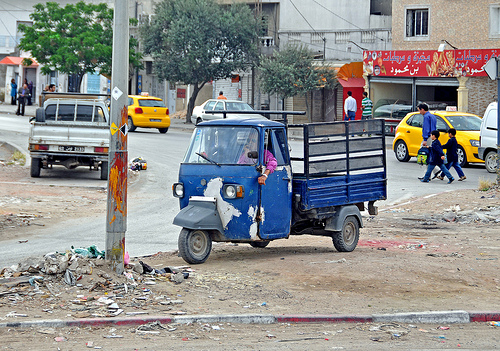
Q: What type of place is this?
A: It is a street.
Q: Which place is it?
A: It is a street.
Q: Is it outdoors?
A: Yes, it is outdoors.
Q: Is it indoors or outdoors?
A: It is outdoors.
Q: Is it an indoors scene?
A: No, it is outdoors.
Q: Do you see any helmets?
A: No, there are no helmets.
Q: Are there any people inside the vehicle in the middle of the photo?
A: Yes, there is a person inside the vehicle.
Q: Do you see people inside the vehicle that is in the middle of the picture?
A: Yes, there is a person inside the vehicle.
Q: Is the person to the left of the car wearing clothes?
A: Yes, the person is wearing clothes.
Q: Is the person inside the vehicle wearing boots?
A: No, the person is wearing clothes.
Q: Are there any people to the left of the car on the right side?
A: Yes, there is a person to the left of the car.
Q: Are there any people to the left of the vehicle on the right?
A: Yes, there is a person to the left of the car.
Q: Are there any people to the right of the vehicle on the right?
A: No, the person is to the left of the car.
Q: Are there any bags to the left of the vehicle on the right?
A: No, there is a person to the left of the car.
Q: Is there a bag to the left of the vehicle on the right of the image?
A: No, there is a person to the left of the car.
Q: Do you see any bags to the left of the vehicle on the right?
A: No, there is a person to the left of the car.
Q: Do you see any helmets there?
A: No, there are no helmets.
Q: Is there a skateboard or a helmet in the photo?
A: No, there are no helmets or skateboards.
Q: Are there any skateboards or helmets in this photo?
A: No, there are no helmets or skateboards.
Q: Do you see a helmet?
A: No, there are no helmets.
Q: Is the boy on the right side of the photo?
A: Yes, the boy is on the right of the image.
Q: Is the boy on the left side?
A: No, the boy is on the right of the image.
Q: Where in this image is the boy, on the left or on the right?
A: The boy is on the right of the image.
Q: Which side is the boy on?
A: The boy is on the right of the image.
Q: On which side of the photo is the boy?
A: The boy is on the right of the image.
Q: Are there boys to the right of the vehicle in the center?
A: Yes, there is a boy to the right of the vehicle.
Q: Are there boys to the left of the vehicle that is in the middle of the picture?
A: No, the boy is to the right of the vehicle.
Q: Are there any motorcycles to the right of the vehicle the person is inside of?
A: No, there is a boy to the right of the vehicle.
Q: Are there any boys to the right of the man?
A: Yes, there is a boy to the right of the man.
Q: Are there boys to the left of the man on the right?
A: No, the boy is to the right of the man.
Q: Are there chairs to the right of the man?
A: No, there is a boy to the right of the man.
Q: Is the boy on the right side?
A: Yes, the boy is on the right of the image.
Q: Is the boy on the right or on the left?
A: The boy is on the right of the image.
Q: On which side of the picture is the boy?
A: The boy is on the right of the image.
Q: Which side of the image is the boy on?
A: The boy is on the right of the image.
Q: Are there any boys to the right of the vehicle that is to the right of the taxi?
A: Yes, there is a boy to the right of the vehicle.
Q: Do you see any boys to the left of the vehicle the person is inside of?
A: No, the boy is to the right of the vehicle.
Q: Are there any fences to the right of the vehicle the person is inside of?
A: No, there is a boy to the right of the vehicle.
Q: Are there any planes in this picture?
A: No, there are no planes.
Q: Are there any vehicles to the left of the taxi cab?
A: No, the vehicle is to the right of the taxi cab.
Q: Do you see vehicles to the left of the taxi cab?
A: No, the vehicle is to the right of the taxi cab.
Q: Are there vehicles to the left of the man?
A: Yes, there is a vehicle to the left of the man.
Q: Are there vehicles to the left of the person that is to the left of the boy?
A: Yes, there is a vehicle to the left of the man.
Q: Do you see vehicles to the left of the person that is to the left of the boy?
A: Yes, there is a vehicle to the left of the man.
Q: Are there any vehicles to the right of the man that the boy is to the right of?
A: No, the vehicle is to the left of the man.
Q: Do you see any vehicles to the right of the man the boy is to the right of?
A: No, the vehicle is to the left of the man.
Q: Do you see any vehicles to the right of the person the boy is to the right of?
A: No, the vehicle is to the left of the man.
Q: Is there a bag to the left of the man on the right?
A: No, there is a vehicle to the left of the man.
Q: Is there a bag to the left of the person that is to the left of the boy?
A: No, there is a vehicle to the left of the man.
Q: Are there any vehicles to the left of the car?
A: Yes, there is a vehicle to the left of the car.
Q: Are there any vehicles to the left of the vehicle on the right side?
A: Yes, there is a vehicle to the left of the car.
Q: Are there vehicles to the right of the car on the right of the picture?
A: No, the vehicle is to the left of the car.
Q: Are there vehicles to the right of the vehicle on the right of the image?
A: No, the vehicle is to the left of the car.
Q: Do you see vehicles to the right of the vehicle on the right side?
A: No, the vehicle is to the left of the car.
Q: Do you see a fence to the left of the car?
A: No, there is a vehicle to the left of the car.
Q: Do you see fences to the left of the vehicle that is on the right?
A: No, there is a vehicle to the left of the car.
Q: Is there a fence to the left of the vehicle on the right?
A: No, there is a vehicle to the left of the car.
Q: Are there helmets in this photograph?
A: No, there are no helmets.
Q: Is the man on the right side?
A: Yes, the man is on the right of the image.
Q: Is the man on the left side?
A: No, the man is on the right of the image.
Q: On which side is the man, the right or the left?
A: The man is on the right of the image.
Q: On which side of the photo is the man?
A: The man is on the right of the image.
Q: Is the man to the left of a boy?
A: Yes, the man is to the left of a boy.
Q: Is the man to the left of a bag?
A: No, the man is to the left of a boy.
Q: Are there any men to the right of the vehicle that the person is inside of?
A: Yes, there is a man to the right of the vehicle.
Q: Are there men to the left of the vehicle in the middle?
A: No, the man is to the right of the vehicle.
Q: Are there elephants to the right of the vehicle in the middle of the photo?
A: No, there is a man to the right of the vehicle.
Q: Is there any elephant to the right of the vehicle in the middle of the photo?
A: No, there is a man to the right of the vehicle.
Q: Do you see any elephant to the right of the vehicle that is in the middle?
A: No, there is a man to the right of the vehicle.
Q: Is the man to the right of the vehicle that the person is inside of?
A: Yes, the man is to the right of the vehicle.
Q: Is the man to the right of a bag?
A: No, the man is to the right of the vehicle.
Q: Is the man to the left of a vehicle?
A: No, the man is to the right of a vehicle.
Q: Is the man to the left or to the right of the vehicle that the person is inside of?
A: The man is to the right of the vehicle.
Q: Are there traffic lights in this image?
A: No, there are no traffic lights.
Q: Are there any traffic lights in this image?
A: No, there are no traffic lights.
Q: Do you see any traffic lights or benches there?
A: No, there are no traffic lights or benches.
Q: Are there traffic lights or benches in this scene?
A: No, there are no traffic lights or benches.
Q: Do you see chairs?
A: No, there are no chairs.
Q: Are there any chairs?
A: No, there are no chairs.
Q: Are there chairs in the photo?
A: No, there are no chairs.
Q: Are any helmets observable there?
A: No, there are no helmets.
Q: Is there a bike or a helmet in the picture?
A: No, there are no helmets or bikes.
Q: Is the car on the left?
A: No, the car is on the right of the image.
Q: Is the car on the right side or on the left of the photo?
A: The car is on the right of the image.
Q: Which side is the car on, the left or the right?
A: The car is on the right of the image.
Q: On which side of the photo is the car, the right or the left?
A: The car is on the right of the image.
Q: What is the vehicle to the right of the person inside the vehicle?
A: The vehicle is a car.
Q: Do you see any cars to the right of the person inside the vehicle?
A: Yes, there is a car to the right of the person.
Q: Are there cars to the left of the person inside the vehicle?
A: No, the car is to the right of the person.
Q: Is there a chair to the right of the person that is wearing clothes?
A: No, there is a car to the right of the person.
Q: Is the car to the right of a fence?
A: No, the car is to the right of the person.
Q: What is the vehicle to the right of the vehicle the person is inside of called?
A: The vehicle is a car.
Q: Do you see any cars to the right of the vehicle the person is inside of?
A: Yes, there is a car to the right of the vehicle.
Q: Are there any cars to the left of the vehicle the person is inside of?
A: No, the car is to the right of the vehicle.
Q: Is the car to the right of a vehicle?
A: Yes, the car is to the right of a vehicle.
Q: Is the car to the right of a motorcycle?
A: No, the car is to the right of a vehicle.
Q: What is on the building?
A: The sign is on the building.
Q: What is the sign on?
A: The sign is on the building.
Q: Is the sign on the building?
A: Yes, the sign is on the building.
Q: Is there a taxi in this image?
A: Yes, there is a taxi.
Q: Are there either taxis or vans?
A: Yes, there is a taxi.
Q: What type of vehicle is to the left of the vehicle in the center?
A: The vehicle is a taxi.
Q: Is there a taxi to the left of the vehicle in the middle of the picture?
A: Yes, there is a taxi to the left of the vehicle.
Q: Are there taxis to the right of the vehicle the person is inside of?
A: No, the taxi is to the left of the vehicle.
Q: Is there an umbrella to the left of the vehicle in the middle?
A: No, there is a taxi to the left of the vehicle.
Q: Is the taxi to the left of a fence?
A: No, the taxi is to the left of the vehicle.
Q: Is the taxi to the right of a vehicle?
A: No, the taxi is to the left of a vehicle.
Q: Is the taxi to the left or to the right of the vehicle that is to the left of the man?
A: The taxi is to the left of the vehicle.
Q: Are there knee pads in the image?
A: No, there are no knee pads.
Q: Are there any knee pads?
A: No, there are no knee pads.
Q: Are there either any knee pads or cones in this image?
A: No, there are no knee pads or cones.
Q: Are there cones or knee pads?
A: No, there are no knee pads or cones.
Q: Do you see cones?
A: No, there are no cones.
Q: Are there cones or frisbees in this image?
A: No, there are no cones or frisbees.